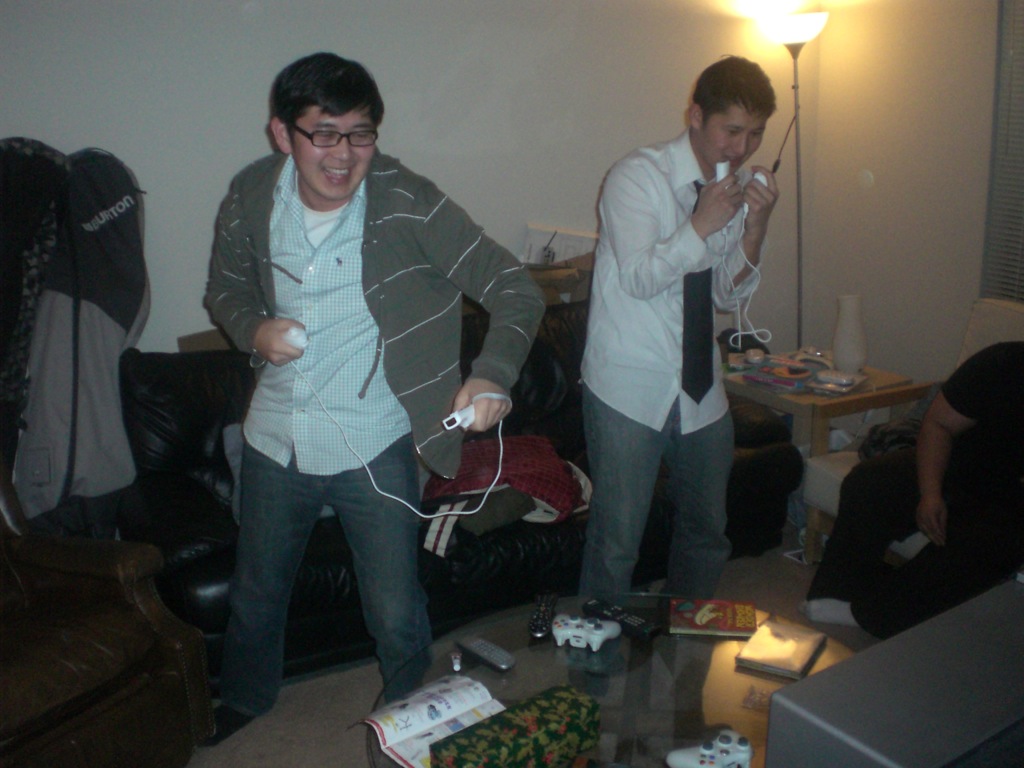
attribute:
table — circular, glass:
[470, 577, 710, 727]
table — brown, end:
[741, 332, 925, 458]